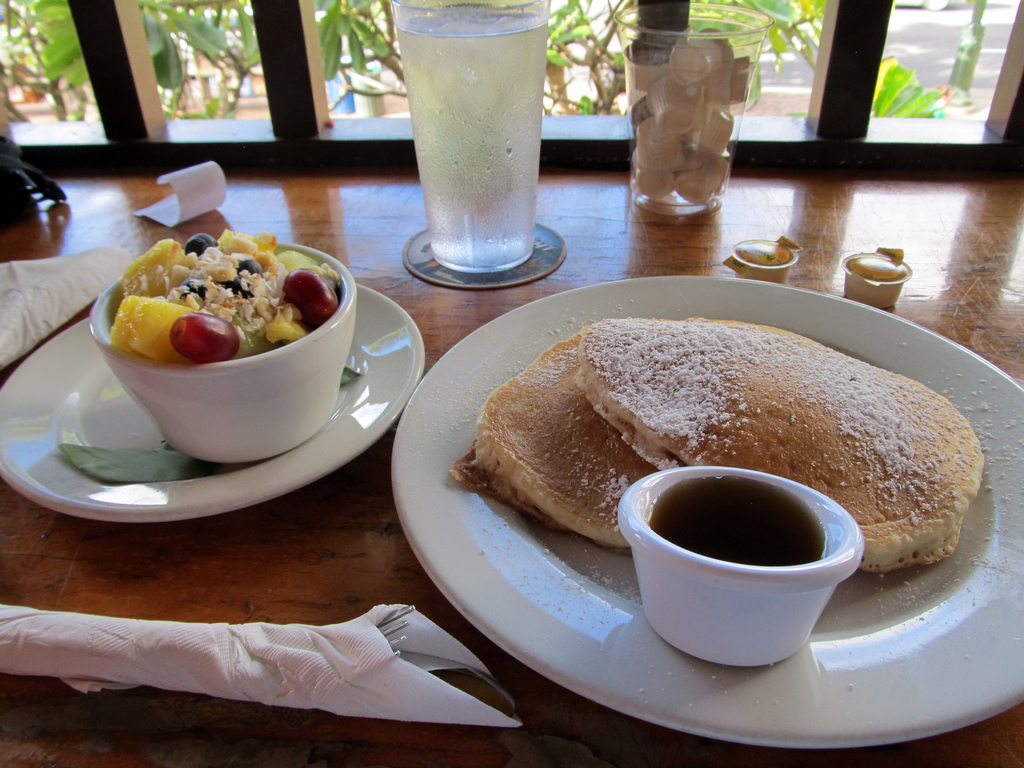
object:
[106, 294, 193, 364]
food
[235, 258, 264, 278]
piece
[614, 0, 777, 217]
cup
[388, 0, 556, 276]
cups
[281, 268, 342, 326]
fruit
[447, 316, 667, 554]
pancake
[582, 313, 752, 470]
powdered sugar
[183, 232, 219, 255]
fruits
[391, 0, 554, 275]
glass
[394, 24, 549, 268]
water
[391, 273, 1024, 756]
plate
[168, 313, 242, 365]
grape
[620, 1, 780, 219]
glass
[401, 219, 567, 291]
coaster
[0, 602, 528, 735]
napkin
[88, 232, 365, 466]
cup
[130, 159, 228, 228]
wrapper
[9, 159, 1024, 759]
table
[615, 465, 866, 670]
container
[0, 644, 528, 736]
knife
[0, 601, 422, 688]
fork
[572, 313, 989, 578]
pancakes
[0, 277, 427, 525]
plate